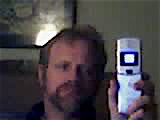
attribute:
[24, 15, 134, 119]
man — holding, taking, bearded, photographing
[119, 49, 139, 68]
display — lit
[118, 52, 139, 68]
rectangle — black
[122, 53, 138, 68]
light — glare, reflecting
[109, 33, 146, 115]
phone — flip, cell, silver, grey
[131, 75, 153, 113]
finger — holding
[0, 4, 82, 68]
picture — blurry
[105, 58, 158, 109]
hand — holding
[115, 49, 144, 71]
screen — small